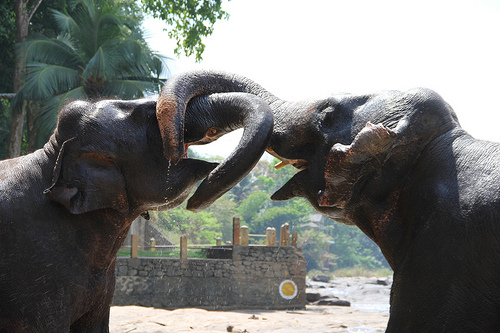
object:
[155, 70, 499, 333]
elephant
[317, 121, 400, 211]
ear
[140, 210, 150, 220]
elephant ear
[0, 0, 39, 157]
gray trunks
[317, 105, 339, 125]
eye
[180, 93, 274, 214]
elephant tusk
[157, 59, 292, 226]
white towels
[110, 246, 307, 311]
stone wall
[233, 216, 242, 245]
wooden post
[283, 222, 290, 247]
wooden post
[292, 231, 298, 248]
wooden post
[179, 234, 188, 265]
wooden post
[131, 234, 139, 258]
wooden post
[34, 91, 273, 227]
head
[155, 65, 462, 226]
head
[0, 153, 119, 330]
body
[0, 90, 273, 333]
elephant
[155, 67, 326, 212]
intertwined trunks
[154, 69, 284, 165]
elephant trunk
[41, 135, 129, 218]
ear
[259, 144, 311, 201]
mouth